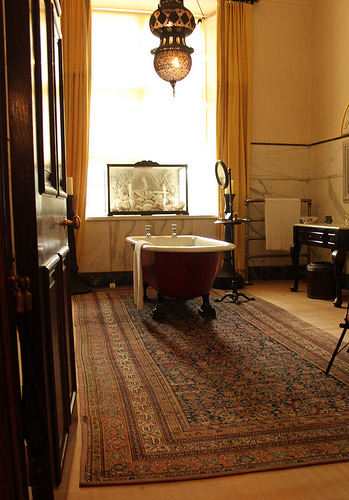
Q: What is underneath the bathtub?
A: A rug.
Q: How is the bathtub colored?
A: Red and white.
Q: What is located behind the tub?
A: Large window.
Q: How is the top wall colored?
A: Beige.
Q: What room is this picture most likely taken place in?
A: Bathroom.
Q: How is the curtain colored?
A: Yellow.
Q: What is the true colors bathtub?
A: Red and white.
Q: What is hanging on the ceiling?
A: Chandelier.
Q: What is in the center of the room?
A: Bathtub.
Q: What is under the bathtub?
A: Rug.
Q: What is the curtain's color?
A: Yellow.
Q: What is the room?
A: Bathroom.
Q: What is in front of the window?
A: Curtain.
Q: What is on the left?
A: Door.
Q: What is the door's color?
A: Brown.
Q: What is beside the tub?
A: Dresser.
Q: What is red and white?
A: Tub.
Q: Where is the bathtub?
A: Middle of the floor.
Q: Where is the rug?
A: Under the tub.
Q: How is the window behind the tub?
A: Large.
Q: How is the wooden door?
A: Open.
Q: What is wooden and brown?
A: Door.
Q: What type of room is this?
A: Bathroom.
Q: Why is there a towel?
A: To dry off.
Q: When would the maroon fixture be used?
A: Bath.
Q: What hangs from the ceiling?
A: Light.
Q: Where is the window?
A: On the back wall.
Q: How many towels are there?
A: 2.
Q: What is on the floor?
A: Rug.